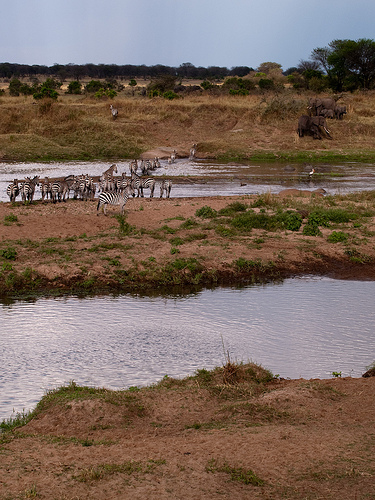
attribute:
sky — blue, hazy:
[0, 1, 374, 75]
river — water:
[0, 156, 375, 206]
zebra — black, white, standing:
[95, 184, 137, 217]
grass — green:
[206, 463, 271, 490]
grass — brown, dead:
[2, 95, 374, 155]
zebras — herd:
[6, 103, 198, 219]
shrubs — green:
[196, 200, 355, 245]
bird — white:
[307, 167, 315, 175]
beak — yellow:
[311, 168, 314, 173]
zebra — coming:
[107, 103, 121, 120]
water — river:
[0, 265, 373, 429]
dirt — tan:
[2, 208, 195, 241]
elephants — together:
[295, 96, 348, 141]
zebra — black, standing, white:
[130, 170, 157, 201]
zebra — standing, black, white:
[6, 179, 21, 204]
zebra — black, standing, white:
[16, 177, 41, 202]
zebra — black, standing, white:
[47, 181, 71, 202]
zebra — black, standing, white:
[158, 177, 172, 198]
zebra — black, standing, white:
[121, 173, 142, 198]